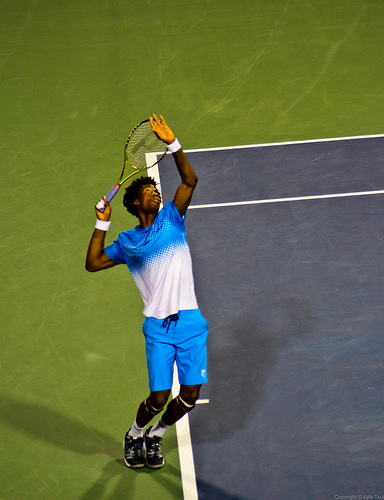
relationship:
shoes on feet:
[122, 425, 146, 471] [119, 427, 168, 465]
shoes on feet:
[59, 391, 218, 497] [117, 426, 171, 467]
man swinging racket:
[77, 113, 211, 472] [94, 117, 168, 212]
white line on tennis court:
[172, 392, 209, 498] [115, 124, 376, 490]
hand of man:
[147, 112, 174, 143] [84, 110, 213, 471]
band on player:
[166, 136, 182, 156] [48, 90, 242, 316]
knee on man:
[179, 384, 202, 405] [84, 110, 213, 471]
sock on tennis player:
[126, 415, 146, 440] [47, 104, 254, 478]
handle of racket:
[94, 179, 121, 213] [83, 110, 171, 208]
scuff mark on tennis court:
[155, 130, 383, 158] [4, 2, 382, 497]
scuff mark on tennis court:
[271, 100, 289, 129] [4, 2, 382, 497]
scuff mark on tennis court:
[155, 130, 383, 158] [142, 130, 382, 495]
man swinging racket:
[84, 110, 213, 471] [91, 113, 172, 215]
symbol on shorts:
[199, 368, 208, 378] [139, 307, 210, 390]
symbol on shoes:
[130, 435, 138, 441] [104, 403, 187, 490]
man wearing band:
[84, 110, 213, 471] [94, 218, 111, 231]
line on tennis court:
[148, 177, 383, 211] [142, 130, 382, 495]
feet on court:
[124, 428, 163, 471] [244, 123, 366, 218]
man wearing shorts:
[84, 110, 213, 471] [121, 294, 253, 405]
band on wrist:
[94, 218, 111, 231] [89, 217, 109, 234]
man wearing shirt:
[84, 110, 213, 471] [103, 199, 206, 317]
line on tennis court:
[185, 185, 384, 213] [0, 0, 383, 499]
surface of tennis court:
[2, 1, 374, 492] [0, 0, 383, 499]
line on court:
[185, 185, 384, 213] [143, 130, 383, 498]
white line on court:
[172, 357, 203, 499] [143, 130, 383, 498]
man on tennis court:
[84, 110, 213, 471] [0, 0, 383, 499]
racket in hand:
[94, 117, 169, 215] [92, 196, 111, 222]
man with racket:
[84, 110, 213, 471] [94, 117, 169, 215]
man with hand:
[84, 110, 213, 471] [92, 196, 111, 222]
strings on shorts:
[151, 314, 190, 328] [96, 267, 236, 409]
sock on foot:
[124, 421, 143, 438] [145, 430, 163, 464]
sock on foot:
[126, 415, 146, 440] [120, 430, 143, 468]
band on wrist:
[166, 136, 182, 156] [173, 138, 183, 161]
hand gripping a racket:
[93, 192, 112, 223] [91, 113, 172, 215]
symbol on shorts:
[200, 368, 206, 378] [139, 307, 210, 390]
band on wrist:
[166, 136, 182, 156] [155, 126, 186, 166]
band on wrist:
[94, 218, 111, 231] [89, 205, 117, 239]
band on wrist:
[160, 134, 181, 157] [165, 141, 185, 161]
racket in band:
[94, 89, 171, 213] [94, 218, 111, 231]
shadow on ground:
[1, 297, 316, 498] [2, 2, 382, 499]